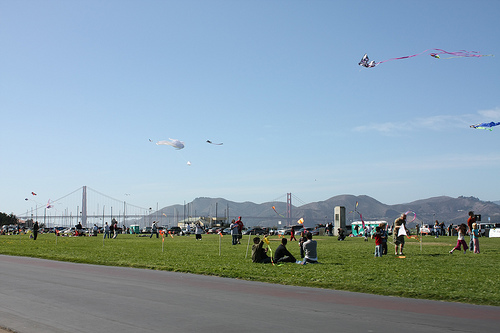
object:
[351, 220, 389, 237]
outhouses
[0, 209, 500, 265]
people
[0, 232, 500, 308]
grass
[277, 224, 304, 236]
vehicle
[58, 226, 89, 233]
vehicle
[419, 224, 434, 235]
vehicle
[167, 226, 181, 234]
vehicle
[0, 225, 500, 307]
field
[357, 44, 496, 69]
kite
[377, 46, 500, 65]
pink tails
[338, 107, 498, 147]
cloud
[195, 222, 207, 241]
person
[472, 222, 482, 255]
person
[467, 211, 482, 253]
person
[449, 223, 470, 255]
person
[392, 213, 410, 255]
person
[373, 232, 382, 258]
person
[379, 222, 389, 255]
person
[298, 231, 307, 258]
person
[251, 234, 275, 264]
person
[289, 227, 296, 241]
person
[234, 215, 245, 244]
person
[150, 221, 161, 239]
person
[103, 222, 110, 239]
person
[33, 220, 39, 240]
person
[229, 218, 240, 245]
person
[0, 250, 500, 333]
road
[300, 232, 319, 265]
person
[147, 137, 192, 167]
kite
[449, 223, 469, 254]
girl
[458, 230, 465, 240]
white top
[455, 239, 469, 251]
burgundy capris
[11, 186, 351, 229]
bridge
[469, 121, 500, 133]
kite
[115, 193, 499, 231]
mountains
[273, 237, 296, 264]
person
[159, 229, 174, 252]
flag